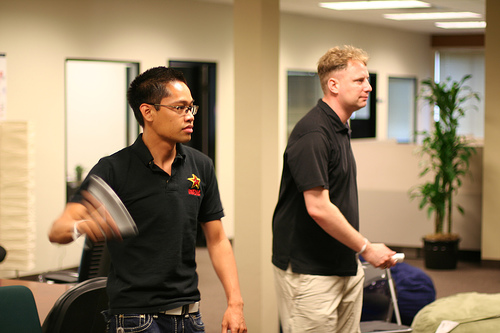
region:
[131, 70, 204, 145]
The man is wearing glasses.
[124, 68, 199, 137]
The man has black hair.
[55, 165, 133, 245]
The man is holding a Wii remote.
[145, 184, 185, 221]
The man is wearing a black shirt.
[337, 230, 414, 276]
The man is holding a Wii remote.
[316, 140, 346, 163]
The man is wearing a black shirt.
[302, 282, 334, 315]
The man is wearing tan pants.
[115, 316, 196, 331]
The man is wearing blue jeans.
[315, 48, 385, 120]
The man's hair is red.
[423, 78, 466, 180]
The leaves on the plant are green.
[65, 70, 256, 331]
the man has glasses on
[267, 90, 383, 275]
the shirt is black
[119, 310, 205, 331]
the jeans are blue in color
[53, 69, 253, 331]
he is playing a game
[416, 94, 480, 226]
the plant is in the photo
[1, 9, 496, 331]
two people are in the room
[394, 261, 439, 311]
the luggage is purple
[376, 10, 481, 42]
light are on the ceiling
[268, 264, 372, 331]
the pants are white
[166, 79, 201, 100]
light is shining on the forehead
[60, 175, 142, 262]
really fast moving hand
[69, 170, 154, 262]
really fast moving hand with Wii-mote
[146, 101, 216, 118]
glasses of an Asian man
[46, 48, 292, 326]
an Asian man playing Wii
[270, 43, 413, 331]
a white man playing Wii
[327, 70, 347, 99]
right ear of white man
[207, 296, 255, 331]
left hand of Asian man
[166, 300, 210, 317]
white belt of Asian man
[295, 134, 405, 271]
right arm of white man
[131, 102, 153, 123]
right ear of Asian man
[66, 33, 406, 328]
two men playing wii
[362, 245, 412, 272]
white wii controller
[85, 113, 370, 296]
two men wearing black collared shirts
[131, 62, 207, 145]
man wearing eye glasses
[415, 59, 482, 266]
tall green house plant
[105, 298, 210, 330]
blue jeans with a white belt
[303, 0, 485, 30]
three lights on ceiling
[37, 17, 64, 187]
walls painted solid white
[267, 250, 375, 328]
man wearing wrinkled khaki pants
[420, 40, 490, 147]
white mini bllinds over window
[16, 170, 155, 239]
the hand is in motion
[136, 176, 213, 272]
a black polo shirt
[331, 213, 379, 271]
the man has a bangle on his hand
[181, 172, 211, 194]
a star is printed in his shirt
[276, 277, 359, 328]
the pants are brown in colour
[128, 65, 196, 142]
the man is wearing spectacles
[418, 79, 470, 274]
the plant is inside a vase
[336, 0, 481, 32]
the lights are on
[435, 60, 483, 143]
the window is closed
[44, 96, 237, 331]
the man is holding a white object